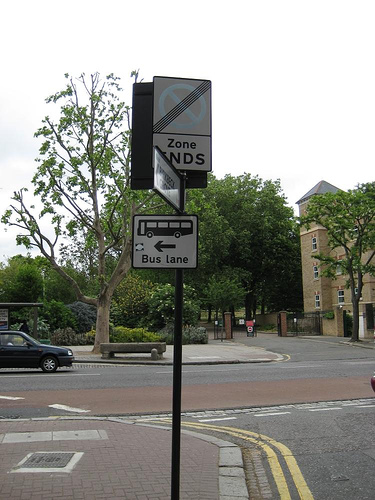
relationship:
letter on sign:
[168, 151, 181, 167] [151, 75, 212, 171]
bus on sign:
[136, 216, 192, 237] [132, 215, 198, 269]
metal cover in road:
[17, 448, 78, 474] [19, 356, 373, 494]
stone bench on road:
[94, 326, 165, 365] [1, 364, 373, 499]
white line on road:
[48, 400, 91, 416] [0, 331, 375, 498]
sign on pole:
[132, 215, 198, 269] [170, 268, 183, 498]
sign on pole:
[152, 147, 183, 209] [170, 268, 183, 498]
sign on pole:
[151, 75, 212, 171] [170, 268, 183, 498]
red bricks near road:
[103, 457, 152, 483] [0, 357, 368, 438]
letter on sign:
[165, 134, 177, 150] [138, 211, 202, 267]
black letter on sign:
[165, 132, 177, 152] [146, 71, 215, 173]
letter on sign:
[194, 150, 205, 165] [151, 75, 212, 171]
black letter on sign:
[140, 251, 148, 264] [128, 211, 200, 269]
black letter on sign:
[195, 149, 207, 167] [146, 71, 215, 173]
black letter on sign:
[162, 252, 170, 267] [128, 211, 200, 269]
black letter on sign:
[182, 252, 190, 267] [128, 211, 200, 269]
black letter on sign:
[165, 132, 177, 152] [147, 141, 186, 210]